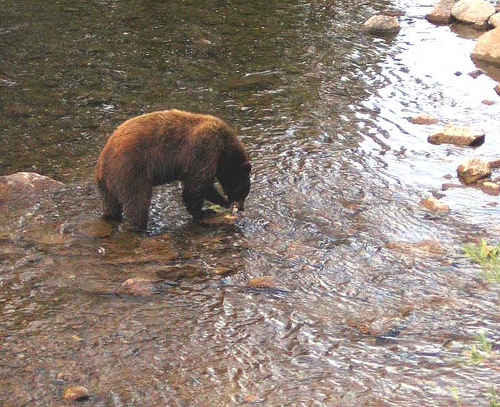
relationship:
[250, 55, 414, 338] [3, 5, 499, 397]
ripples in water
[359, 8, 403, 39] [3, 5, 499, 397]
rock on river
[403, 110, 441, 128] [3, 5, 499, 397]
rock in river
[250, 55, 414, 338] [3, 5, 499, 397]
ripples in river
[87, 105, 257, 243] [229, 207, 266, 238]
bear looking down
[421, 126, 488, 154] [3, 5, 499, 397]
rock on water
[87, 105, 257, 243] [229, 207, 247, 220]
bear eating a food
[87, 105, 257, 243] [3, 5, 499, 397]
bear fishing in a stream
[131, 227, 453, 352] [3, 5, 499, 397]
rocks below water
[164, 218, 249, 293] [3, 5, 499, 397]
reflection on water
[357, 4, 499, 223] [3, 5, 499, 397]
rocks jutting out water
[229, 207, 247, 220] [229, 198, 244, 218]
food in mouth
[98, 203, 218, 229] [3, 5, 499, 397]
legs in water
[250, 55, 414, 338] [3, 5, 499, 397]
ripples on surface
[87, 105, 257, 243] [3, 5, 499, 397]
bear in a stream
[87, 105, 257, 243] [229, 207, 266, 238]
bear looking for food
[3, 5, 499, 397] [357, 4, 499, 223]
stream has rocks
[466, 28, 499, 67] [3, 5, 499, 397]
rock on top stream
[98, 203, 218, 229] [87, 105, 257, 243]
legs of bear